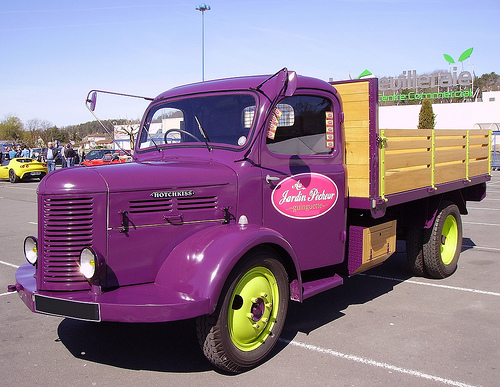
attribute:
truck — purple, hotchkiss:
[6, 68, 491, 375]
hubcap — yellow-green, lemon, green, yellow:
[228, 267, 280, 351]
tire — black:
[198, 252, 293, 376]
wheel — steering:
[163, 126, 200, 145]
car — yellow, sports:
[0, 155, 46, 185]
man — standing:
[42, 141, 56, 172]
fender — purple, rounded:
[153, 220, 301, 295]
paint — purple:
[17, 70, 349, 323]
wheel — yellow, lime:
[424, 202, 462, 279]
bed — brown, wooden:
[378, 125, 492, 197]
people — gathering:
[6, 140, 87, 169]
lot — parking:
[0, 143, 499, 385]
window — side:
[266, 91, 335, 156]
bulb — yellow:
[31, 246, 38, 253]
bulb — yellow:
[89, 258, 94, 269]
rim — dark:
[23, 236, 30, 264]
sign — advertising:
[378, 91, 474, 102]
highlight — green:
[457, 47, 473, 63]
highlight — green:
[442, 52, 456, 66]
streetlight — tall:
[192, 1, 211, 84]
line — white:
[281, 335, 477, 386]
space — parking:
[279, 271, 496, 385]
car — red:
[83, 154, 129, 167]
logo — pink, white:
[270, 170, 340, 220]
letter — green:
[432, 91, 443, 101]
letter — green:
[387, 94, 394, 102]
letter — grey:
[154, 193, 160, 198]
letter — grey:
[184, 190, 188, 196]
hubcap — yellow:
[439, 217, 456, 266]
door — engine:
[90, 157, 241, 230]